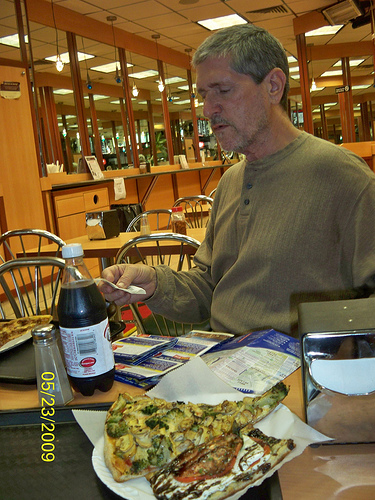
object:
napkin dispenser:
[296, 297, 375, 444]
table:
[2, 331, 373, 499]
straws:
[45, 159, 66, 173]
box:
[48, 170, 69, 187]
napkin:
[92, 275, 147, 300]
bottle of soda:
[55, 240, 118, 397]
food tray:
[1, 401, 283, 498]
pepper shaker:
[30, 321, 76, 409]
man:
[99, 21, 374, 333]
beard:
[209, 106, 275, 154]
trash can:
[113, 200, 146, 232]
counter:
[49, 157, 231, 206]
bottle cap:
[61, 240, 86, 261]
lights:
[46, 5, 196, 106]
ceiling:
[3, 3, 374, 98]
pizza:
[154, 432, 296, 499]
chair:
[114, 231, 205, 336]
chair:
[3, 258, 82, 320]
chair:
[126, 206, 190, 230]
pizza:
[0, 314, 53, 349]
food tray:
[0, 319, 125, 389]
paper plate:
[88, 393, 294, 499]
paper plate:
[2, 324, 53, 352]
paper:
[72, 354, 332, 499]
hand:
[101, 262, 157, 308]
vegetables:
[140, 403, 186, 435]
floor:
[3, 275, 67, 320]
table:
[18, 227, 206, 261]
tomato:
[177, 440, 241, 482]